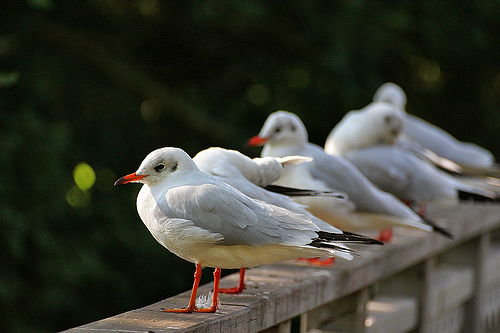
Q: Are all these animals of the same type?
A: Yes, all the animals are birds.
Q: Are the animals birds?
A: Yes, all the animals are birds.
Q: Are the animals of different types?
A: No, all the animals are birds.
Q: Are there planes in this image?
A: No, there are no planes.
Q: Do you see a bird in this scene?
A: Yes, there is a bird.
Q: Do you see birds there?
A: Yes, there is a bird.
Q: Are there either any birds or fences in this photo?
A: Yes, there is a bird.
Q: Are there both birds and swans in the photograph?
A: No, there is a bird but no swans.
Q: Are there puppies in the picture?
A: No, there are no puppies.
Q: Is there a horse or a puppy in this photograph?
A: No, there are no puppies or horses.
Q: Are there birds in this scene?
A: Yes, there is a bird.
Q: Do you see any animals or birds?
A: Yes, there is a bird.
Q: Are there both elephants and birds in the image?
A: No, there is a bird but no elephants.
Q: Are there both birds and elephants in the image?
A: No, there is a bird but no elephants.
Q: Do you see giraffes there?
A: No, there are no giraffes.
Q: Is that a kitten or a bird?
A: That is a bird.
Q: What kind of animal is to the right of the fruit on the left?
A: The animal is a bird.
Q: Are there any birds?
A: Yes, there is a bird.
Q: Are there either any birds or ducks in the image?
A: Yes, there is a bird.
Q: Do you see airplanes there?
A: No, there are no airplanes.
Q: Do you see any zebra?
A: No, there are no zebras.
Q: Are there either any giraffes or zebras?
A: No, there are no zebras or giraffes.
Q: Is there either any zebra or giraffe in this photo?
A: No, there are no zebras or giraffes.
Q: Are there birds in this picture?
A: Yes, there is a bird.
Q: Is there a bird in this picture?
A: Yes, there is a bird.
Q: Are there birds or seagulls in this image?
A: Yes, there is a bird.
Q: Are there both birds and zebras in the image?
A: No, there is a bird but no zebras.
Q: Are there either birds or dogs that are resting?
A: Yes, the bird is resting.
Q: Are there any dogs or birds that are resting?
A: Yes, the bird is resting.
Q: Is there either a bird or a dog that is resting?
A: Yes, the bird is resting.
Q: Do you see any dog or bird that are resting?
A: Yes, the bird is resting.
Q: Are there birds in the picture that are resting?
A: Yes, there is a bird that is resting.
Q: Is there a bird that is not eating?
A: Yes, there is a bird that is resting.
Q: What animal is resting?
A: The animal is a bird.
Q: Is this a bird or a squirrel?
A: This is a bird.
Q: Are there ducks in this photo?
A: No, there are no ducks.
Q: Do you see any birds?
A: Yes, there is a bird.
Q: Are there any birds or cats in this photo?
A: Yes, there is a bird.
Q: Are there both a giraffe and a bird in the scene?
A: No, there is a bird but no giraffes.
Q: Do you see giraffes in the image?
A: No, there are no giraffes.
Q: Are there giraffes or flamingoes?
A: No, there are no giraffes or flamingoes.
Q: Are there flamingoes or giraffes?
A: No, there are no giraffes or flamingoes.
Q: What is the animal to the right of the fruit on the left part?
A: The animal is a bird.